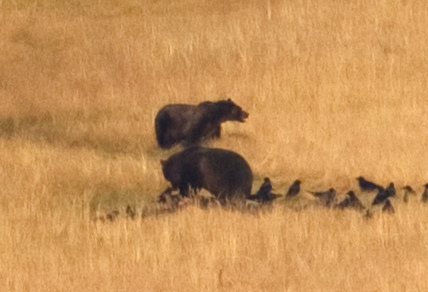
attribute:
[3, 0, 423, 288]
field — brown, grassy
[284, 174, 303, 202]
bird — small, black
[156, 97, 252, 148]
bear — brown, standing, small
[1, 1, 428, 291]
grass — brown, tan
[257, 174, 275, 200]
duck — black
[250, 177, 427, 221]
birds — black